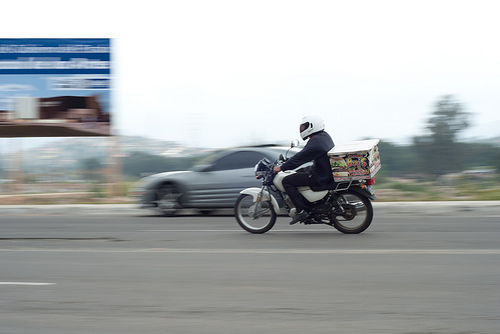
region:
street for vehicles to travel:
[21, 223, 462, 320]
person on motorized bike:
[248, 119, 367, 237]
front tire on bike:
[235, 181, 280, 222]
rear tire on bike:
[331, 181, 373, 228]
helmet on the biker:
[291, 111, 321, 136]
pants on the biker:
[283, 171, 316, 207]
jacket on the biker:
[288, 138, 335, 174]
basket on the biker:
[324, 135, 379, 184]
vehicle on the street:
[136, 133, 330, 209]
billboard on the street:
[6, 20, 151, 170]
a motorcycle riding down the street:
[236, 113, 441, 273]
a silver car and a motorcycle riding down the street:
[135, 97, 441, 254]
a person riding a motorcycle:
[228, 117, 393, 244]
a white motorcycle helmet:
[293, 112, 328, 141]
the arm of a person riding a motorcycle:
[270, 142, 321, 174]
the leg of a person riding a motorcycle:
[282, 171, 317, 226]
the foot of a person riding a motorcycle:
[289, 205, 308, 226]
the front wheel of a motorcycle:
[233, 186, 279, 236]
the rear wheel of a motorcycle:
[330, 190, 375, 235]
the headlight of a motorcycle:
[248, 156, 267, 181]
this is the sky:
[188, 32, 400, 87]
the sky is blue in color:
[169, 32, 281, 124]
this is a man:
[293, 118, 330, 200]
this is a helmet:
[299, 115, 324, 127]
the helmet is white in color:
[311, 112, 324, 130]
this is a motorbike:
[331, 182, 376, 232]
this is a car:
[157, 152, 231, 218]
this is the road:
[307, 252, 454, 321]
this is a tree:
[421, 87, 473, 164]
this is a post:
[3, 35, 130, 137]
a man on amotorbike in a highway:
[228, 113, 408, 254]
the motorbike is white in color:
[256, 180, 283, 208]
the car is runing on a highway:
[147, 144, 226, 208]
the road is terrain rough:
[236, 243, 396, 313]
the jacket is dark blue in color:
[294, 148, 324, 177]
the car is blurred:
[91, 140, 194, 236]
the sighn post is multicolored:
[10, 46, 91, 125]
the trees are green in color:
[425, 120, 467, 163]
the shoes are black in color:
[296, 208, 309, 220]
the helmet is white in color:
[301, 117, 337, 134]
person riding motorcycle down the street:
[14, 46, 493, 331]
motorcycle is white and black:
[231, 148, 382, 239]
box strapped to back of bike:
[310, 120, 392, 198]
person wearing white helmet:
[280, 106, 331, 145]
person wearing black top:
[275, 131, 333, 188]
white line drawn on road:
[8, 190, 497, 327]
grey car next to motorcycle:
[128, 76, 436, 243]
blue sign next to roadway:
[2, 33, 163, 219]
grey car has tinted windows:
[128, 131, 321, 230]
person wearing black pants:
[263, 165, 320, 205]